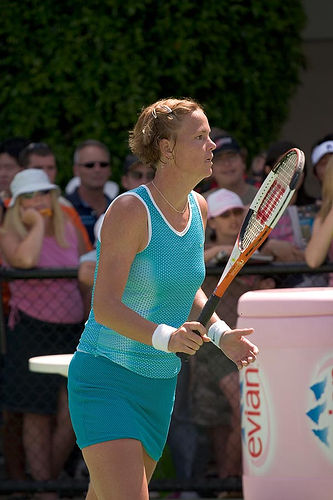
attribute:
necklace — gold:
[152, 181, 188, 217]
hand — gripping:
[167, 320, 210, 355]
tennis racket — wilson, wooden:
[179, 147, 305, 363]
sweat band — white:
[144, 319, 241, 353]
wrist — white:
[149, 320, 180, 361]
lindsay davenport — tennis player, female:
[65, 96, 260, 498]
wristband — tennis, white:
[151, 321, 178, 353]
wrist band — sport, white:
[149, 320, 180, 356]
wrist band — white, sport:
[205, 316, 232, 348]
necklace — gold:
[140, 151, 201, 224]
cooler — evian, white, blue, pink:
[216, 274, 331, 414]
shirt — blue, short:
[76, 183, 205, 377]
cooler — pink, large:
[235, 286, 332, 499]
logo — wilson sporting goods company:
[255, 179, 284, 224]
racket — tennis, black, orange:
[198, 133, 302, 268]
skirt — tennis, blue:
[67, 350, 179, 462]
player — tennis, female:
[53, 120, 227, 409]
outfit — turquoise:
[64, 193, 217, 450]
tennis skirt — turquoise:
[68, 350, 177, 459]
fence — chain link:
[7, 255, 327, 431]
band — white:
[147, 321, 177, 352]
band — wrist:
[144, 314, 177, 363]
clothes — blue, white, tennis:
[62, 178, 210, 468]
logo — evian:
[231, 362, 273, 471]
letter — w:
[253, 177, 286, 224]